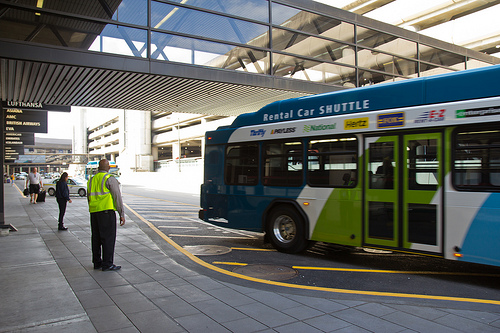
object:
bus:
[197, 63, 497, 268]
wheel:
[263, 197, 311, 254]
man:
[84, 153, 129, 270]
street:
[0, 261, 499, 332]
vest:
[82, 171, 122, 216]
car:
[39, 175, 92, 196]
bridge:
[2, 5, 499, 115]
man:
[25, 165, 39, 206]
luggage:
[22, 187, 48, 203]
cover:
[177, 243, 230, 257]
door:
[366, 134, 444, 252]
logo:
[250, 129, 271, 138]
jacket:
[55, 181, 73, 203]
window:
[305, 136, 358, 188]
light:
[301, 198, 312, 210]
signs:
[0, 99, 51, 163]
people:
[24, 157, 135, 270]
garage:
[76, 0, 492, 171]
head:
[96, 158, 113, 173]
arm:
[107, 175, 129, 227]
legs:
[87, 212, 128, 272]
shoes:
[89, 261, 125, 275]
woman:
[54, 170, 76, 231]